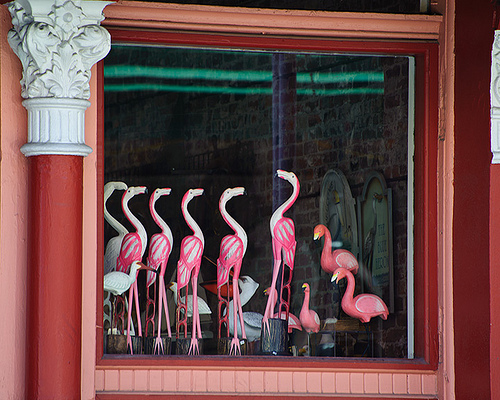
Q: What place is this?
A: It is a display.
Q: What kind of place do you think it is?
A: It is a display.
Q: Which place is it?
A: It is a display.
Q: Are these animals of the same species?
A: No, there are both flamingoes and birds.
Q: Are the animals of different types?
A: Yes, they are flamingoes and birds.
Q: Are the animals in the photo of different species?
A: Yes, they are flamingoes and birds.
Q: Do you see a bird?
A: Yes, there is a bird.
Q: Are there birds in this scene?
A: Yes, there is a bird.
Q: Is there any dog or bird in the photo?
A: Yes, there is a bird.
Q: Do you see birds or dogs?
A: Yes, there is a bird.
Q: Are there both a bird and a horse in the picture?
A: No, there is a bird but no horses.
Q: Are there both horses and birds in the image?
A: No, there is a bird but no horses.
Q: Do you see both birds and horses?
A: No, there is a bird but no horses.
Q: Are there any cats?
A: No, there are no cats.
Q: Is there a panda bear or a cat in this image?
A: No, there are no cats or panda bears.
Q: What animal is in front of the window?
A: The bird is in front of the window.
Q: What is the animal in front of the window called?
A: The animal is a bird.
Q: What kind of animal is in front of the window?
A: The animal is a bird.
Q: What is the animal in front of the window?
A: The animal is a bird.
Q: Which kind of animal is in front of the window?
A: The animal is a bird.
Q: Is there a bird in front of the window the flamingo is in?
A: Yes, there is a bird in front of the window.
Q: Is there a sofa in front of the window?
A: No, there is a bird in front of the window.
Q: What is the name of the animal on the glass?
A: The animal is a bird.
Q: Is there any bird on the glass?
A: Yes, there is a bird on the glass.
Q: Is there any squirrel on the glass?
A: No, there is a bird on the glass.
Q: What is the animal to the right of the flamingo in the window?
A: The animal is a bird.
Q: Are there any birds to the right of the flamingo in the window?
A: Yes, there is a bird to the right of the flamingo.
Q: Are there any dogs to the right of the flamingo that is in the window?
A: No, there is a bird to the right of the flamingo.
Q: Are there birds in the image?
A: Yes, there is a bird.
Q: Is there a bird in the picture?
A: Yes, there is a bird.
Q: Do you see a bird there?
A: Yes, there is a bird.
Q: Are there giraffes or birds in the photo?
A: Yes, there is a bird.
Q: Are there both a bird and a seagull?
A: No, there is a bird but no seagulls.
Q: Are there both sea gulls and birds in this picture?
A: No, there is a bird but no seagulls.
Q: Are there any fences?
A: No, there are no fences.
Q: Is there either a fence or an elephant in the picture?
A: No, there are no fences or elephants.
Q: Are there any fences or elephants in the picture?
A: No, there are no fences or elephants.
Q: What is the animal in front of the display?
A: The animal is a bird.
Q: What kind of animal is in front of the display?
A: The animal is a bird.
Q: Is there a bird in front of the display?
A: Yes, there is a bird in front of the display.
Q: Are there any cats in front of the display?
A: No, there is a bird in front of the display.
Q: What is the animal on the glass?
A: The animal is a bird.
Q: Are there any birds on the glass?
A: Yes, there is a bird on the glass.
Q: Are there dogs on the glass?
A: No, there is a bird on the glass.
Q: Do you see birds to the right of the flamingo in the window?
A: Yes, there is a bird to the right of the flamingo.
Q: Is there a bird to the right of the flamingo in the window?
A: Yes, there is a bird to the right of the flamingo.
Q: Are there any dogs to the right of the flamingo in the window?
A: No, there is a bird to the right of the flamingo.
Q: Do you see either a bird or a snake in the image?
A: Yes, there is a bird.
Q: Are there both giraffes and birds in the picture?
A: No, there is a bird but no giraffes.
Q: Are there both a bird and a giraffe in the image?
A: No, there is a bird but no giraffes.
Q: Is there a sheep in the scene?
A: No, there is no sheep.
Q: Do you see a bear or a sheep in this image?
A: No, there are no sheep or bears.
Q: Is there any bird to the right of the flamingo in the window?
A: Yes, there is a bird to the right of the flamingo.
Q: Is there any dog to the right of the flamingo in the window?
A: No, there is a bird to the right of the flamingo.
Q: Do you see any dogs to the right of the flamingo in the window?
A: No, there is a bird to the right of the flamingo.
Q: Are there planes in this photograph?
A: No, there are no planes.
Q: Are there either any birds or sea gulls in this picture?
A: Yes, there is a bird.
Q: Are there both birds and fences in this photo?
A: No, there is a bird but no fences.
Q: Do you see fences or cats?
A: No, there are no cats or fences.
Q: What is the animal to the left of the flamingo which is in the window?
A: The animal is a bird.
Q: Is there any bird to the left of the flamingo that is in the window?
A: Yes, there is a bird to the left of the flamingo.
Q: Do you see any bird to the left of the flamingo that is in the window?
A: Yes, there is a bird to the left of the flamingo.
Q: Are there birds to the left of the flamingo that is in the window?
A: Yes, there is a bird to the left of the flamingo.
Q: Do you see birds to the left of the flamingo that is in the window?
A: Yes, there is a bird to the left of the flamingo.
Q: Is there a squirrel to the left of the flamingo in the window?
A: No, there is a bird to the left of the flamingo.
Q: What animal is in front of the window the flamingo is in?
A: The bird is in front of the window.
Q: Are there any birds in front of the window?
A: Yes, there is a bird in front of the window.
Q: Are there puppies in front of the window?
A: No, there is a bird in front of the window.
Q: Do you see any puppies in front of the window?
A: No, there is a bird in front of the window.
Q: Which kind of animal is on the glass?
A: The animal is a bird.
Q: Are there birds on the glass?
A: Yes, there is a bird on the glass.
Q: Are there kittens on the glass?
A: No, there is a bird on the glass.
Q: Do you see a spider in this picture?
A: No, there are no spiders.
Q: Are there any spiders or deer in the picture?
A: No, there are no spiders or deer.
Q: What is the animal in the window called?
A: The animal is a flamingo.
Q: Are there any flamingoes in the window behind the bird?
A: Yes, there is a flamingo in the window.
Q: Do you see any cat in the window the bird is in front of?
A: No, there is a flamingo in the window.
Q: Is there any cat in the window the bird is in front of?
A: No, there is a flamingo in the window.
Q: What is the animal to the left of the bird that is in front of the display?
A: The animal is a flamingo.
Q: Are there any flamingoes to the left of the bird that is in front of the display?
A: Yes, there is a flamingo to the left of the bird.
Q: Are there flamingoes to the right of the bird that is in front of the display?
A: No, the flamingo is to the left of the bird.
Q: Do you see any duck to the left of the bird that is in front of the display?
A: No, there is a flamingo to the left of the bird.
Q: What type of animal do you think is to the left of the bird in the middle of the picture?
A: The animal is a flamingo.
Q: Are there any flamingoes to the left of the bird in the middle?
A: Yes, there is a flamingo to the left of the bird.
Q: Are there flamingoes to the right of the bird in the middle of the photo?
A: No, the flamingo is to the left of the bird.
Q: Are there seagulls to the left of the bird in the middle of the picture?
A: No, there is a flamingo to the left of the bird.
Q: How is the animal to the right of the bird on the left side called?
A: The animal is a flamingo.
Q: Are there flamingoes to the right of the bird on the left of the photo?
A: Yes, there is a flamingo to the right of the bird.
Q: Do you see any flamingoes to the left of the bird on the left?
A: No, the flamingo is to the right of the bird.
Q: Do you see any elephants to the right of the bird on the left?
A: No, there is a flamingo to the right of the bird.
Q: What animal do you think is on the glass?
A: The animal is a flamingo.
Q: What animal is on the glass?
A: The animal is a flamingo.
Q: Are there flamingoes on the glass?
A: Yes, there is a flamingo on the glass.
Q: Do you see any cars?
A: No, there are no cars.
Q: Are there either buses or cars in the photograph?
A: No, there are no cars or buses.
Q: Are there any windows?
A: Yes, there is a window.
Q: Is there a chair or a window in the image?
A: Yes, there is a window.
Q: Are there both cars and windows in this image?
A: No, there is a window but no cars.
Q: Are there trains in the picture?
A: No, there are no trains.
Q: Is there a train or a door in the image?
A: No, there are no trains or doors.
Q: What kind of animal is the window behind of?
A: The window is behind the bird.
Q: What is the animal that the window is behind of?
A: The animal is a bird.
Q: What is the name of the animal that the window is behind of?
A: The animal is a bird.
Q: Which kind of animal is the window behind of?
A: The window is behind the bird.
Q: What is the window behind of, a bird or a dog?
A: The window is behind a bird.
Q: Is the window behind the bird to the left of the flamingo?
A: Yes, the window is behind the bird.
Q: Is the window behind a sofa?
A: No, the window is behind the bird.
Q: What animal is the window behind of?
A: The window is behind the bird.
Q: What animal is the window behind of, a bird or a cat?
A: The window is behind a bird.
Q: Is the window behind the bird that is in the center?
A: Yes, the window is behind the bird.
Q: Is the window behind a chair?
A: No, the window is behind the bird.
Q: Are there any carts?
A: No, there are no carts.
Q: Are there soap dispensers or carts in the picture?
A: No, there are no carts or soap dispensers.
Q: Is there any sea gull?
A: No, there are no seagulls.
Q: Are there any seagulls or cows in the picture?
A: No, there are no seagulls or cows.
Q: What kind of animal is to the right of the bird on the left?
A: The animal is a flamingo.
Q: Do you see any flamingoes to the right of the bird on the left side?
A: Yes, there is a flamingo to the right of the bird.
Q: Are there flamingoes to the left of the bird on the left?
A: No, the flamingo is to the right of the bird.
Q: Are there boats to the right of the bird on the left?
A: No, there is a flamingo to the right of the bird.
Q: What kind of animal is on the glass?
A: The animal is a flamingo.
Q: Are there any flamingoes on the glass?
A: Yes, there is a flamingo on the glass.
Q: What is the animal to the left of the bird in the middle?
A: The animal is a flamingo.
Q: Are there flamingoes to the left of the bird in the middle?
A: Yes, there is a flamingo to the left of the bird.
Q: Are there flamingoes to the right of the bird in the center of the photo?
A: No, the flamingo is to the left of the bird.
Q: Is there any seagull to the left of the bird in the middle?
A: No, there is a flamingo to the left of the bird.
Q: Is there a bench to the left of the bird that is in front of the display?
A: No, there is a flamingo to the left of the bird.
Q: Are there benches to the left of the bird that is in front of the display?
A: No, there is a flamingo to the left of the bird.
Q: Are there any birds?
A: Yes, there is a bird.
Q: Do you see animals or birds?
A: Yes, there is a bird.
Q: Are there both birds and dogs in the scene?
A: No, there is a bird but no dogs.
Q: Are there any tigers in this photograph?
A: No, there are no tigers.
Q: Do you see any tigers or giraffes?
A: No, there are no tigers or giraffes.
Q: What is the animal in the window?
A: The animal is a bird.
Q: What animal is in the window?
A: The animal is a bird.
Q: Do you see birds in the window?
A: Yes, there is a bird in the window.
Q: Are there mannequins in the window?
A: No, there is a bird in the window.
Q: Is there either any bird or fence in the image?
A: Yes, there is a bird.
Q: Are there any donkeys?
A: No, there are no donkeys.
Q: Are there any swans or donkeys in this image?
A: No, there are no donkeys or swans.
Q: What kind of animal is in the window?
A: The animal is a bird.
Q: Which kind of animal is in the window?
A: The animal is a bird.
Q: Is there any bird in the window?
A: Yes, there is a bird in the window.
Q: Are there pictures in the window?
A: No, there is a bird in the window.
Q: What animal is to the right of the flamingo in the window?
A: The animal is a bird.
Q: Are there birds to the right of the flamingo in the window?
A: Yes, there is a bird to the right of the flamingo.